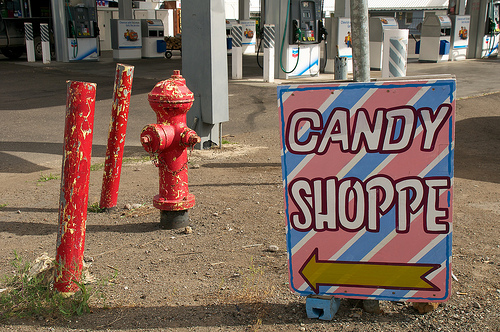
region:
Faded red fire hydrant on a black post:
[140, 66, 204, 233]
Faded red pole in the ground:
[48, 75, 99, 300]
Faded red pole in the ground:
[95, 57, 141, 217]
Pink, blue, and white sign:
[270, 83, 463, 320]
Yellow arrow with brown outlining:
[293, 248, 443, 296]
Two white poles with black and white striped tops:
[19, 19, 54, 66]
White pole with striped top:
[226, 21, 249, 81]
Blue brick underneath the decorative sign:
[302, 291, 339, 321]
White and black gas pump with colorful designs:
[267, 0, 329, 79]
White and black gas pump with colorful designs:
[52, 0, 107, 60]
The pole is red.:
[46, 73, 98, 301]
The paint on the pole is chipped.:
[48, 75, 105, 303]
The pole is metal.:
[48, 68, 104, 321]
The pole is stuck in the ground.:
[34, 66, 98, 310]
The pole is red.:
[98, 58, 135, 223]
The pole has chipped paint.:
[103, 52, 138, 233]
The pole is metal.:
[103, 55, 130, 247]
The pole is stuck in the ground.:
[94, 43, 129, 221]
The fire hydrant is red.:
[138, 63, 213, 240]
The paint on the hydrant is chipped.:
[141, 60, 200, 242]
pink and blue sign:
[337, 53, 372, 210]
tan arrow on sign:
[302, 243, 387, 287]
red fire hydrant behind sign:
[166, 150, 202, 203]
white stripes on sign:
[311, 223, 367, 276]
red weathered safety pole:
[69, 102, 97, 166]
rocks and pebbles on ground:
[171, 219, 206, 257]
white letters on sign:
[308, 178, 393, 238]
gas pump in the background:
[282, 25, 329, 72]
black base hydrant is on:
[156, 203, 203, 244]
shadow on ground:
[22, 83, 40, 128]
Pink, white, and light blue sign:
[277, 75, 454, 300]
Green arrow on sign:
[300, 245, 445, 292]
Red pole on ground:
[50, 78, 95, 293]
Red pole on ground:
[98, 61, 135, 207]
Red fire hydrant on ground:
[139, 71, 199, 228]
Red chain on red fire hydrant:
[143, 138, 197, 178]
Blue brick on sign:
[305, 293, 343, 319]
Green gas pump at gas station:
[279, 0, 301, 75]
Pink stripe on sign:
[288, 101, 455, 291]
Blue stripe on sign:
[301, 150, 452, 295]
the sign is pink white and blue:
[270, 70, 460, 315]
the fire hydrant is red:
[136, 67, 196, 217]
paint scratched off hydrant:
[136, 70, 206, 220]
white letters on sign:
[287, 107, 463, 239]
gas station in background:
[1, 4, 498, 144]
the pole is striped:
[258, 19, 275, 50]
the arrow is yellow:
[287, 240, 437, 295]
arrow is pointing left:
[291, 235, 441, 301]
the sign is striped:
[273, 86, 455, 304]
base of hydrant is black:
[151, 202, 201, 237]